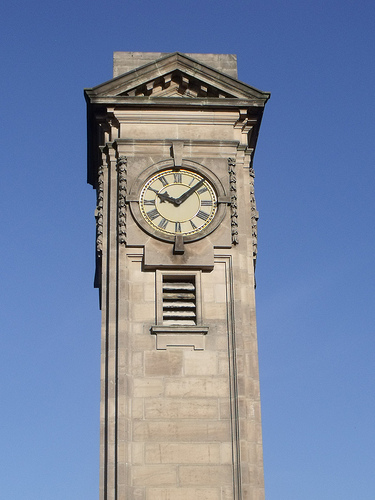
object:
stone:
[205, 378, 227, 397]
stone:
[145, 441, 159, 462]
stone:
[132, 377, 146, 397]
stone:
[132, 398, 145, 419]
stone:
[179, 440, 208, 464]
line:
[203, 417, 206, 440]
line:
[215, 397, 218, 419]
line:
[159, 439, 220, 444]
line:
[173, 464, 179, 486]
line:
[129, 440, 134, 463]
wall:
[100, 109, 263, 497]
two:
[197, 185, 210, 191]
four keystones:
[124, 141, 232, 256]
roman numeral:
[144, 182, 159, 199]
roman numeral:
[143, 206, 161, 224]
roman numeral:
[198, 197, 213, 211]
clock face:
[138, 167, 219, 236]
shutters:
[158, 272, 201, 323]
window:
[154, 267, 203, 331]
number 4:
[194, 207, 211, 226]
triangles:
[109, 66, 241, 100]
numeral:
[170, 218, 185, 237]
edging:
[175, 51, 273, 99]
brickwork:
[82, 49, 271, 498]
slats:
[157, 280, 199, 294]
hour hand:
[154, 188, 176, 210]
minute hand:
[174, 174, 207, 208]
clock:
[125, 155, 228, 244]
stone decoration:
[113, 152, 131, 247]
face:
[124, 141, 232, 255]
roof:
[82, 47, 273, 112]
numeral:
[171, 172, 187, 186]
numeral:
[155, 171, 172, 188]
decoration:
[223, 153, 244, 249]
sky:
[3, 0, 375, 498]